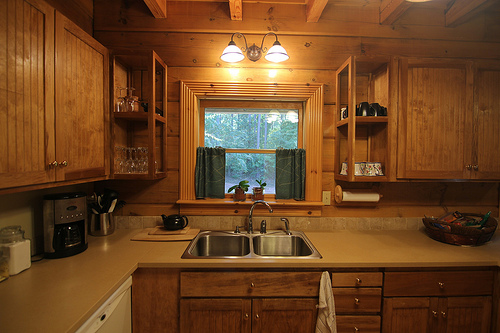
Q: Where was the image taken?
A: It was taken at the kitchen.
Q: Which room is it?
A: It is a kitchen.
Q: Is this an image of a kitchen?
A: Yes, it is showing a kitchen.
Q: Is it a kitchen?
A: Yes, it is a kitchen.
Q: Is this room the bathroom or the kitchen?
A: It is the kitchen.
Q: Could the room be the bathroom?
A: No, it is the kitchen.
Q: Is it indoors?
A: Yes, it is indoors.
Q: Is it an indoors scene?
A: Yes, it is indoors.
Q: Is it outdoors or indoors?
A: It is indoors.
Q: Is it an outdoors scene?
A: No, it is indoors.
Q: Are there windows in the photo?
A: Yes, there is a window.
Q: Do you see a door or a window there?
A: Yes, there is a window.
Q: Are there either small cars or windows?
A: Yes, there is a small window.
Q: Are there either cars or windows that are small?
A: Yes, the window is small.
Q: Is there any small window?
A: Yes, there is a small window.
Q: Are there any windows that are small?
A: Yes, there is a window that is small.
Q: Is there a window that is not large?
A: Yes, there is a small window.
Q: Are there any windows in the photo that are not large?
A: Yes, there is a small window.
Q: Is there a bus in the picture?
A: No, there are no buses.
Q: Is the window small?
A: Yes, the window is small.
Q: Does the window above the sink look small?
A: Yes, the window is small.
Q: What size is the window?
A: The window is small.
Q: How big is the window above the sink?
A: The window is small.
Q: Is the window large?
A: No, the window is small.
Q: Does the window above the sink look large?
A: No, the window is small.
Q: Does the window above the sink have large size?
A: No, the window is small.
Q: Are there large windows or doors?
A: No, there is a window but it is small.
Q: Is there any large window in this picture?
A: No, there is a window but it is small.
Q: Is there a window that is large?
A: No, there is a window but it is small.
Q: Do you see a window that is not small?
A: No, there is a window but it is small.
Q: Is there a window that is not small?
A: No, there is a window but it is small.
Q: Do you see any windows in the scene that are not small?
A: No, there is a window but it is small.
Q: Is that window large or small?
A: The window is small.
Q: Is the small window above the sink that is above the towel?
A: Yes, the window is above the sink.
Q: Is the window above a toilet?
A: No, the window is above the sink.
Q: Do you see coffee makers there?
A: Yes, there is a coffee maker.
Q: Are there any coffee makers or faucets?
A: Yes, there is a coffee maker.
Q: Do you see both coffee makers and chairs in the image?
A: No, there is a coffee maker but no chairs.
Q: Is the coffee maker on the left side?
A: Yes, the coffee maker is on the left of the image.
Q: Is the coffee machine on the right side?
A: No, the coffee machine is on the left of the image.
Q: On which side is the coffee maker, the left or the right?
A: The coffee maker is on the left of the image.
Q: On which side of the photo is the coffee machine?
A: The coffee machine is on the left of the image.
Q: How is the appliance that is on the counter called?
A: The appliance is a coffee maker.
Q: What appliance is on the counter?
A: The appliance is a coffee maker.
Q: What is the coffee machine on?
A: The coffee machine is on the counter.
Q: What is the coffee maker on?
A: The coffee machine is on the counter.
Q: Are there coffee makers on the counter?
A: Yes, there is a coffee maker on the counter.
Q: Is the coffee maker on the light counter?
A: Yes, the coffee maker is on the counter.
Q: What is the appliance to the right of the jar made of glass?
A: The appliance is a coffee maker.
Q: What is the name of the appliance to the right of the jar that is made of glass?
A: The appliance is a coffee maker.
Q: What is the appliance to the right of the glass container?
A: The appliance is a coffee maker.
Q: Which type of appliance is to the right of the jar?
A: The appliance is a coffee maker.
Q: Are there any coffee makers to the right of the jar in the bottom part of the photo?
A: Yes, there is a coffee maker to the right of the jar.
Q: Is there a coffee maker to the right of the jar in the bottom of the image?
A: Yes, there is a coffee maker to the right of the jar.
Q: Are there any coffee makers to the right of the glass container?
A: Yes, there is a coffee maker to the right of the jar.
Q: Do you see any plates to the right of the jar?
A: No, there is a coffee maker to the right of the jar.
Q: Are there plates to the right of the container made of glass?
A: No, there is a coffee maker to the right of the jar.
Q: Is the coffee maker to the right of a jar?
A: Yes, the coffee maker is to the right of a jar.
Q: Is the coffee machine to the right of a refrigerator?
A: No, the coffee machine is to the right of a jar.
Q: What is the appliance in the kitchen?
A: The appliance is a coffee maker.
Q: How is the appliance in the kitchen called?
A: The appliance is a coffee maker.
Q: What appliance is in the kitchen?
A: The appliance is a coffee maker.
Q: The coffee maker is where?
A: The coffee maker is in the kitchen.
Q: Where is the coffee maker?
A: The coffee maker is in the kitchen.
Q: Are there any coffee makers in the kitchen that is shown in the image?
A: Yes, there is a coffee maker in the kitchen.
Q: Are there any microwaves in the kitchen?
A: No, there is a coffee maker in the kitchen.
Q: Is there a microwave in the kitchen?
A: No, there is a coffee maker in the kitchen.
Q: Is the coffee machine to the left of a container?
A: Yes, the coffee machine is to the left of a container.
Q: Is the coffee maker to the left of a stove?
A: No, the coffee maker is to the left of a container.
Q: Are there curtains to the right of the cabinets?
A: Yes, there are curtains to the right of the cabinets.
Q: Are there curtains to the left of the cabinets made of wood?
A: No, the curtains are to the right of the cabinets.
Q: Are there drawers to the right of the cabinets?
A: No, there are curtains to the right of the cabinets.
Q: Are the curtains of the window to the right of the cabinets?
A: Yes, the curtains are to the right of the cabinets.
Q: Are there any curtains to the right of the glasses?
A: Yes, there are curtains to the right of the glasses.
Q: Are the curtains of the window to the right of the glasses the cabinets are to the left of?
A: Yes, the curtains are to the right of the glasses.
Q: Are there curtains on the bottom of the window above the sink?
A: Yes, there are curtains on the bottom of the window.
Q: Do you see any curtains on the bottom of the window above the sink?
A: Yes, there are curtains on the bottom of the window.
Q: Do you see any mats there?
A: No, there are no mats.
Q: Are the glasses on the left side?
A: Yes, the glasses are on the left of the image.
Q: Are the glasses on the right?
A: No, the glasses are on the left of the image.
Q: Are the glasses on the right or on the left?
A: The glasses are on the left of the image.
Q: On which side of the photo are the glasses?
A: The glasses are on the left of the image.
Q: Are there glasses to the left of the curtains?
A: Yes, there are glasses to the left of the curtains.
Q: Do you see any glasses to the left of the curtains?
A: Yes, there are glasses to the left of the curtains.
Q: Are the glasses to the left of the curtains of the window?
A: Yes, the glasses are to the left of the curtains.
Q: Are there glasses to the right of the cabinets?
A: Yes, there are glasses to the right of the cabinets.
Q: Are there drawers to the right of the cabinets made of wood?
A: No, there are glasses to the right of the cabinets.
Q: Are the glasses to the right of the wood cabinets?
A: Yes, the glasses are to the right of the cabinets.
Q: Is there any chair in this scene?
A: No, there are no chairs.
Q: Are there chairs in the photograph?
A: No, there are no chairs.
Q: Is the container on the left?
A: Yes, the container is on the left of the image.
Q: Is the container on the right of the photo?
A: No, the container is on the left of the image.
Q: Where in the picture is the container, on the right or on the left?
A: The container is on the left of the image.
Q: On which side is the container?
A: The container is on the left of the image.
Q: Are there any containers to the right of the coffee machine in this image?
A: Yes, there is a container to the right of the coffee machine.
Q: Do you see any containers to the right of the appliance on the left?
A: Yes, there is a container to the right of the coffee machine.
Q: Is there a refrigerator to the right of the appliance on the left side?
A: No, there is a container to the right of the coffee machine.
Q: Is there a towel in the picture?
A: Yes, there is a towel.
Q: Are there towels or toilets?
A: Yes, there is a towel.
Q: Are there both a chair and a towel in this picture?
A: No, there is a towel but no chairs.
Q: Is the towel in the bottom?
A: Yes, the towel is in the bottom of the image.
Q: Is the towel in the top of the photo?
A: No, the towel is in the bottom of the image.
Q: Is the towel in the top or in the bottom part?
A: The towel is in the bottom of the image.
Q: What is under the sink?
A: The towel is under the sink.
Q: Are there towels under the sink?
A: Yes, there is a towel under the sink.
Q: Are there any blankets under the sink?
A: No, there is a towel under the sink.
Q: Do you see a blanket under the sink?
A: No, there is a towel under the sink.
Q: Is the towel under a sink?
A: Yes, the towel is under a sink.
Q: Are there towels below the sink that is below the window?
A: Yes, there is a towel below the sink.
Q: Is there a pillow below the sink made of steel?
A: No, there is a towel below the sink.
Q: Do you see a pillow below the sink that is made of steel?
A: No, there is a towel below the sink.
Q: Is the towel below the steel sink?
A: Yes, the towel is below the sink.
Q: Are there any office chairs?
A: No, there are no office chairs.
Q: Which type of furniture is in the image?
A: The furniture is cabinets.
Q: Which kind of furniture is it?
A: The pieces of furniture are cabinets.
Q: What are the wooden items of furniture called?
A: The pieces of furniture are cabinets.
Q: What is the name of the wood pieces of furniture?
A: The pieces of furniture are cabinets.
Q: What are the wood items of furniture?
A: The pieces of furniture are cabinets.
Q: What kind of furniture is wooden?
A: The furniture is cabinets.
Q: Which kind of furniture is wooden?
A: The furniture is cabinets.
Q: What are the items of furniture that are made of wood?
A: The pieces of furniture are cabinets.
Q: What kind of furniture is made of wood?
A: The furniture is cabinets.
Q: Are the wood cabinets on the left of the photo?
A: Yes, the cabinets are on the left of the image.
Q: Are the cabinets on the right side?
A: No, the cabinets are on the left of the image.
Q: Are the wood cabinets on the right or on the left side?
A: The cabinets are on the left of the image.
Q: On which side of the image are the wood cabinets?
A: The cabinets are on the left of the image.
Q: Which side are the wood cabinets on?
A: The cabinets are on the left of the image.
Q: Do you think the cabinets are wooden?
A: Yes, the cabinets are wooden.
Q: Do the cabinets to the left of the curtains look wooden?
A: Yes, the cabinets are wooden.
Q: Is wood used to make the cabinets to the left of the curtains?
A: Yes, the cabinets are made of wood.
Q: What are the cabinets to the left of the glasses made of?
A: The cabinets are made of wood.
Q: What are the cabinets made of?
A: The cabinets are made of wood.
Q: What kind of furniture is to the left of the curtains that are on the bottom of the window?
A: The pieces of furniture are cabinets.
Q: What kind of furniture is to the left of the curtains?
A: The pieces of furniture are cabinets.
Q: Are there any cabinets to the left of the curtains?
A: Yes, there are cabinets to the left of the curtains.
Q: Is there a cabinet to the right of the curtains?
A: No, the cabinets are to the left of the curtains.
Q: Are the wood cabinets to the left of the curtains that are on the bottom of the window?
A: Yes, the cabinets are to the left of the curtains.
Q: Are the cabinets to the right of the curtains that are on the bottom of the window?
A: No, the cabinets are to the left of the curtains.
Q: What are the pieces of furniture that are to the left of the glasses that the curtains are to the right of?
A: The pieces of furniture are cabinets.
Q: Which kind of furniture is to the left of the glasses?
A: The pieces of furniture are cabinets.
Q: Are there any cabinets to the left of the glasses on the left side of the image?
A: Yes, there are cabinets to the left of the glasses.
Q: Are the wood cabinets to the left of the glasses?
A: Yes, the cabinets are to the left of the glasses.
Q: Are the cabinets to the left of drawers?
A: No, the cabinets are to the left of the glasses.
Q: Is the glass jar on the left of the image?
A: Yes, the jar is on the left of the image.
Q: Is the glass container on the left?
A: Yes, the jar is on the left of the image.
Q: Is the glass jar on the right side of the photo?
A: No, the jar is on the left of the image.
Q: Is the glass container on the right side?
A: No, the jar is on the left of the image.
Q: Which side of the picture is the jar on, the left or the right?
A: The jar is on the left of the image.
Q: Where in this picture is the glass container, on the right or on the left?
A: The jar is on the left of the image.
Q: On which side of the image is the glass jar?
A: The jar is on the left of the image.